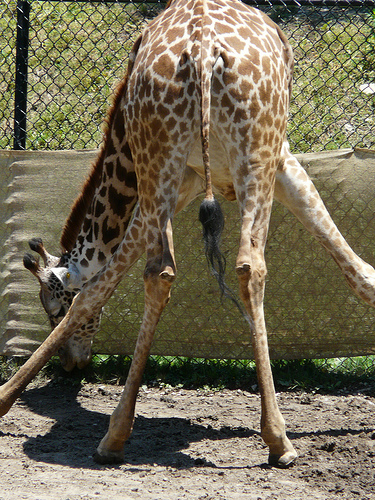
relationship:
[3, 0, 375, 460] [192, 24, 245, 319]
animal has tail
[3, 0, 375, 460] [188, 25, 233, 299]
animal has tail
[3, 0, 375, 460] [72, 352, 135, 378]
animal eating grass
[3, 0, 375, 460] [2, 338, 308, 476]
animal with feet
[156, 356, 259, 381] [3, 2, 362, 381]
grass on or side of fence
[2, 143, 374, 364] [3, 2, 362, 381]
cloth lining bottom of a fence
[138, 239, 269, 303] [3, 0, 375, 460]
knobby knees of a animal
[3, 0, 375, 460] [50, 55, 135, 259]
animal with mane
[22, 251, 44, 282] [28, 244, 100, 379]
horns on her head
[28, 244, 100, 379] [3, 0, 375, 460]
head of animal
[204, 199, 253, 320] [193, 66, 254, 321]
hair on end of tail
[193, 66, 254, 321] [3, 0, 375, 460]
tail of animal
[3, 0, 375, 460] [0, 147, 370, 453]
animal splaying legs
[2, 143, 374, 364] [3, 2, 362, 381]
cloth covering a fence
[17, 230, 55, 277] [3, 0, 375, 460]
horns on animal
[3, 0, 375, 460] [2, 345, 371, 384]
animal eating grass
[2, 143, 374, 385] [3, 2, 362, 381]
cloth alongside base of fence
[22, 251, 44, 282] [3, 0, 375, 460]
horns on animal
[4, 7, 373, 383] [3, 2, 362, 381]
area behind fence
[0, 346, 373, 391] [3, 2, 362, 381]
grass coming through fence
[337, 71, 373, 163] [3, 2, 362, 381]
rocks behind fence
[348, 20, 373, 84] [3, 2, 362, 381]
bush behind fence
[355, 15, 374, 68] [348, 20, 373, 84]
branches of bush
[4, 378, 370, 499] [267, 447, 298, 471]
sand on feet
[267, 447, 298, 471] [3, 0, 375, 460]
feet of animal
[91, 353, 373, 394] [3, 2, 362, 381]
grass under fence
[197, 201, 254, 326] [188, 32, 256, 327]
hair on tail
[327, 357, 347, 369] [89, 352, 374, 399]
object on grass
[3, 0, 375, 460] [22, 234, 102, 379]
animal has head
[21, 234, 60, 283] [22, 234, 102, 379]
horns on head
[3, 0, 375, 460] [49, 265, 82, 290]
animal has ear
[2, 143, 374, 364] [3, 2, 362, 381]
cloth on fence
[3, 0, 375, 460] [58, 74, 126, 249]
animal has mane